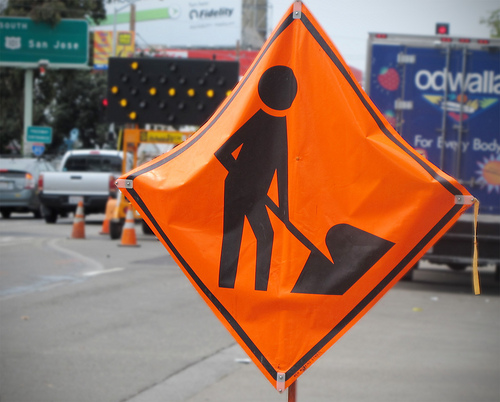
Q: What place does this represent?
A: It represents the pavement.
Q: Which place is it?
A: It is a pavement.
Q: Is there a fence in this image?
A: No, there are no fences.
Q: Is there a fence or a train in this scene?
A: No, there are no fences or trains.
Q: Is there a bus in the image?
A: No, there are no buses.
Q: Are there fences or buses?
A: No, there are no buses or fences.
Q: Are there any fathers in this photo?
A: No, there are no fathers.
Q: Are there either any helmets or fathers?
A: No, there are no fathers or helmets.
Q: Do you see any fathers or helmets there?
A: No, there are no fathers or helmets.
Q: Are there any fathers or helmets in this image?
A: No, there are no fathers or helmets.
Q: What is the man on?
A: The man is on the sign.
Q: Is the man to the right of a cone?
A: Yes, the man is to the right of a cone.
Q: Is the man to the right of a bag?
A: No, the man is to the right of a cone.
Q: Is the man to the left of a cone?
A: No, the man is to the right of a cone.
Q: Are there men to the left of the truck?
A: Yes, there is a man to the left of the truck.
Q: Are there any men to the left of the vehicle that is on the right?
A: Yes, there is a man to the left of the truck.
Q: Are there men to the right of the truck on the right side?
A: No, the man is to the left of the truck.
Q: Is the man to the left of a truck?
A: Yes, the man is to the left of a truck.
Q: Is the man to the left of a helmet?
A: No, the man is to the left of a truck.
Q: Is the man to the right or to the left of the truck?
A: The man is to the left of the truck.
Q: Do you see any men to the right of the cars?
A: Yes, there is a man to the right of the cars.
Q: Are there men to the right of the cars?
A: Yes, there is a man to the right of the cars.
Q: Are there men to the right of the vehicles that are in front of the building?
A: Yes, there is a man to the right of the cars.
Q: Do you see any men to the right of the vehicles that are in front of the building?
A: Yes, there is a man to the right of the cars.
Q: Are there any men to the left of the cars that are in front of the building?
A: No, the man is to the right of the cars.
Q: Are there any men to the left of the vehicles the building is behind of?
A: No, the man is to the right of the cars.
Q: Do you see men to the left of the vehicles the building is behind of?
A: No, the man is to the right of the cars.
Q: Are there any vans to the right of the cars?
A: No, there is a man to the right of the cars.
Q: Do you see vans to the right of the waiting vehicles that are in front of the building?
A: No, there is a man to the right of the cars.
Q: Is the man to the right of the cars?
A: Yes, the man is to the right of the cars.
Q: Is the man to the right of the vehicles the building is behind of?
A: Yes, the man is to the right of the cars.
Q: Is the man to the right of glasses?
A: No, the man is to the right of the cars.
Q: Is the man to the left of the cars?
A: No, the man is to the right of the cars.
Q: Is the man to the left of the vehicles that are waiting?
A: No, the man is to the right of the cars.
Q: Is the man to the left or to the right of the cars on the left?
A: The man is to the right of the cars.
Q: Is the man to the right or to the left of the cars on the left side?
A: The man is to the right of the cars.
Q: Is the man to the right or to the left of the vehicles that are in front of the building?
A: The man is to the right of the cars.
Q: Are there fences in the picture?
A: No, there are no fences.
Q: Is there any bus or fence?
A: No, there are no fences or buses.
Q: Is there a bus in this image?
A: No, there are no buses.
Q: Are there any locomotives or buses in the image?
A: No, there are no buses or locomotives.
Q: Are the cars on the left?
A: Yes, the cars are on the left of the image.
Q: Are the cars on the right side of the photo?
A: No, the cars are on the left of the image.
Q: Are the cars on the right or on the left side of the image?
A: The cars are on the left of the image.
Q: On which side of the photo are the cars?
A: The cars are on the left of the image.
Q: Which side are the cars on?
A: The cars are on the left of the image.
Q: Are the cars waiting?
A: Yes, the cars are waiting.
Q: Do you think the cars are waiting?
A: Yes, the cars are waiting.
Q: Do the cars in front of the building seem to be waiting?
A: Yes, the cars are waiting.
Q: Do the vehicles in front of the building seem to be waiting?
A: Yes, the cars are waiting.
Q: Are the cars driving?
A: No, the cars are waiting.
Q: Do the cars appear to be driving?
A: No, the cars are waiting.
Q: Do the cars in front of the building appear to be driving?
A: No, the cars are waiting.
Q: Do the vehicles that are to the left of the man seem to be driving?
A: No, the cars are waiting.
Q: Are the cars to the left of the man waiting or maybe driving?
A: The cars are waiting.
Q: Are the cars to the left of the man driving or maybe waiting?
A: The cars are waiting.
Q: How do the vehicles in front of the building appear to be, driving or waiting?
A: The cars are waiting.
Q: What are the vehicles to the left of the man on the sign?
A: The vehicles are cars.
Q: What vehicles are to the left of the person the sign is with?
A: The vehicles are cars.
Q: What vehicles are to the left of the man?
A: The vehicles are cars.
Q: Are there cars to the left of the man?
A: Yes, there are cars to the left of the man.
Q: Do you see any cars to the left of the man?
A: Yes, there are cars to the left of the man.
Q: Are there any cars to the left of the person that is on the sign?
A: Yes, there are cars to the left of the man.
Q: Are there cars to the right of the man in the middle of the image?
A: No, the cars are to the left of the man.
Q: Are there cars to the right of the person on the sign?
A: No, the cars are to the left of the man.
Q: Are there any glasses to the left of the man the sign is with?
A: No, there are cars to the left of the man.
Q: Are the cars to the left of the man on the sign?
A: Yes, the cars are to the left of the man.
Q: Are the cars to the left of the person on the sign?
A: Yes, the cars are to the left of the man.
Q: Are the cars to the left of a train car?
A: No, the cars are to the left of the man.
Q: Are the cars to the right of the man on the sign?
A: No, the cars are to the left of the man.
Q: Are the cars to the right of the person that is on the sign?
A: No, the cars are to the left of the man.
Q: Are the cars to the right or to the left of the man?
A: The cars are to the left of the man.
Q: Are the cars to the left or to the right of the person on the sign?
A: The cars are to the left of the man.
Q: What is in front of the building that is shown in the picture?
A: The cars are in front of the building.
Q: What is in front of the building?
A: The cars are in front of the building.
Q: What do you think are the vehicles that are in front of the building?
A: The vehicles are cars.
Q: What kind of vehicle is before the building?
A: The vehicles are cars.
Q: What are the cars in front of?
A: The cars are in front of the building.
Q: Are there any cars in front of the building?
A: Yes, there are cars in front of the building.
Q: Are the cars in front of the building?
A: Yes, the cars are in front of the building.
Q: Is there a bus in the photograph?
A: No, there are no buses.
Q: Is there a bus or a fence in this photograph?
A: No, there are no buses or fences.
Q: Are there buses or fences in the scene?
A: No, there are no buses or fences.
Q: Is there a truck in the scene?
A: Yes, there is a truck.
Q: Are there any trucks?
A: Yes, there is a truck.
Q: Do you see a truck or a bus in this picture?
A: Yes, there is a truck.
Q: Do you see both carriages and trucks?
A: No, there is a truck but no carriages.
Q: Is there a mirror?
A: No, there are no mirrors.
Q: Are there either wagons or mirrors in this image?
A: No, there are no mirrors or wagons.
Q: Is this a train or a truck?
A: This is a truck.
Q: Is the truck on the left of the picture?
A: No, the truck is on the right of the image.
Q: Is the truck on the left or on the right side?
A: The truck is on the right of the image.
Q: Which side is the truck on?
A: The truck is on the right of the image.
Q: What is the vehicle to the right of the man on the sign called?
A: The vehicle is a truck.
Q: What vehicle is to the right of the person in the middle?
A: The vehicle is a truck.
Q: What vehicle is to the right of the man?
A: The vehicle is a truck.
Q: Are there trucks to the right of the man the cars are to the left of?
A: Yes, there is a truck to the right of the man.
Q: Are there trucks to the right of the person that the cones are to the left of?
A: Yes, there is a truck to the right of the man.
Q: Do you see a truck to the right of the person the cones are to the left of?
A: Yes, there is a truck to the right of the man.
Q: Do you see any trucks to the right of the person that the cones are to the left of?
A: Yes, there is a truck to the right of the man.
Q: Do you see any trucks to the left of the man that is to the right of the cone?
A: No, the truck is to the right of the man.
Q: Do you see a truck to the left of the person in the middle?
A: No, the truck is to the right of the man.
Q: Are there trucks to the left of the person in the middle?
A: No, the truck is to the right of the man.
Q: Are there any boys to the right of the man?
A: No, there is a truck to the right of the man.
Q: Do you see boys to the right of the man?
A: No, there is a truck to the right of the man.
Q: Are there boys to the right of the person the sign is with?
A: No, there is a truck to the right of the man.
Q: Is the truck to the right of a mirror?
A: No, the truck is to the right of a man.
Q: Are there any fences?
A: No, there are no fences.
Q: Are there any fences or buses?
A: No, there are no fences or buses.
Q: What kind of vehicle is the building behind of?
A: The building is behind the cars.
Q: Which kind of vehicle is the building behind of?
A: The building is behind the cars.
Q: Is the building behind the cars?
A: Yes, the building is behind the cars.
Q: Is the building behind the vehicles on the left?
A: Yes, the building is behind the cars.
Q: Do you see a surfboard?
A: No, there are no surfboards.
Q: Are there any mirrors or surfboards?
A: No, there are no surfboards or mirrors.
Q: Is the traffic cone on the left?
A: Yes, the traffic cone is on the left of the image.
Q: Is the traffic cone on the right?
A: No, the traffic cone is on the left of the image.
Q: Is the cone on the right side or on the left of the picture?
A: The cone is on the left of the image.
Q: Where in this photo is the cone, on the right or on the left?
A: The cone is on the left of the image.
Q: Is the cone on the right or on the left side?
A: The cone is on the left of the image.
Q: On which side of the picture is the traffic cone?
A: The traffic cone is on the left of the image.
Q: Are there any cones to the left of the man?
A: Yes, there is a cone to the left of the man.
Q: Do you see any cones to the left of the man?
A: Yes, there is a cone to the left of the man.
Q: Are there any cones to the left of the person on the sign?
A: Yes, there is a cone to the left of the man.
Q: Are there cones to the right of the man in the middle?
A: No, the cone is to the left of the man.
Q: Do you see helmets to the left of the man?
A: No, there is a cone to the left of the man.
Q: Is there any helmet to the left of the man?
A: No, there is a cone to the left of the man.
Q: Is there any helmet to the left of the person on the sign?
A: No, there is a cone to the left of the man.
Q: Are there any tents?
A: No, there are no tents.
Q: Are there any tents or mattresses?
A: No, there are no tents or mattresses.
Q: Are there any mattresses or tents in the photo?
A: No, there are no tents or mattresses.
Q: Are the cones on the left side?
A: Yes, the cones are on the left of the image.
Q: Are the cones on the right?
A: No, the cones are on the left of the image.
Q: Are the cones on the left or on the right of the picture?
A: The cones are on the left of the image.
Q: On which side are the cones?
A: The cones are on the left of the image.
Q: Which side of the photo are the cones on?
A: The cones are on the left of the image.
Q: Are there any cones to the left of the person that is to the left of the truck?
A: Yes, there are cones to the left of the man.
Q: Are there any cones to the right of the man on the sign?
A: No, the cones are to the left of the man.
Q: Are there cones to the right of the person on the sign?
A: No, the cones are to the left of the man.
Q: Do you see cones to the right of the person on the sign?
A: No, the cones are to the left of the man.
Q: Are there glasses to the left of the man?
A: No, there are cones to the left of the man.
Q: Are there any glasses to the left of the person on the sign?
A: No, there are cones to the left of the man.